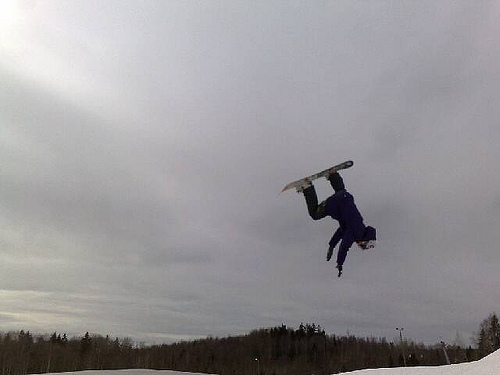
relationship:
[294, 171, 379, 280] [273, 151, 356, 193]
person on snowboard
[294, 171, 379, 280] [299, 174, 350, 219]
person wears pants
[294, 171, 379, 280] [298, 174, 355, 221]
person wears pants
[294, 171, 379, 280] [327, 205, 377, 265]
person wears jacket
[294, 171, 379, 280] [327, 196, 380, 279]
person wears jacket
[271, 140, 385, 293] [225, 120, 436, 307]
person in air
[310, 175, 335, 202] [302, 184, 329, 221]
square opening formed by leg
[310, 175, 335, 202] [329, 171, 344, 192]
square opening formed by leg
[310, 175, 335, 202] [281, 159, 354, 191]
square opening formed by snowboard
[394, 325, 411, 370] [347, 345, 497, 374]
pole on mountain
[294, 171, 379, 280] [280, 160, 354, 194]
person on snowboard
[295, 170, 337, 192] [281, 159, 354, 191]
feet on snowboard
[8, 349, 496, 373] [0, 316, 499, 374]
snow of hill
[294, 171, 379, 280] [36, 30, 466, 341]
person in air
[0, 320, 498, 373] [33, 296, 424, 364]
trees cover hills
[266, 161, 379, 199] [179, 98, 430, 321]
snowboard in air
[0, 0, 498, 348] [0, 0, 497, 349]
clouds in overcast sky